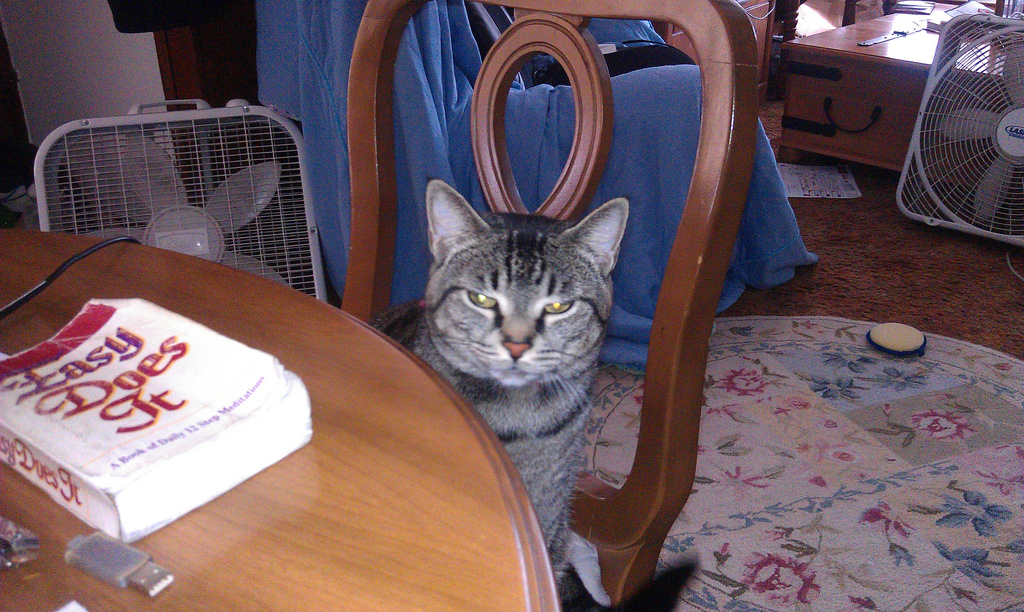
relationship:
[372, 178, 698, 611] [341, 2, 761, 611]
cat sitting on chair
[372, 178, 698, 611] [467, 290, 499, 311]
cat with eye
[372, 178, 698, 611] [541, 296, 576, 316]
cat with eye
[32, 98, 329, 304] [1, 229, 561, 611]
box fan sitting behind table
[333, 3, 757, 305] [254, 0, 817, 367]
chair covered in blanket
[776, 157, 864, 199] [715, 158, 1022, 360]
paper sitting on floor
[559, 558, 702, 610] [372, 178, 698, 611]
tail of cat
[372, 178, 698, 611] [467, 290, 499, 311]
cat has eye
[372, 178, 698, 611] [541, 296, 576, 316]
cat has eye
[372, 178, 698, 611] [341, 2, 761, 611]
cat sitting in chair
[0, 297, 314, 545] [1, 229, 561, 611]
book sitting on table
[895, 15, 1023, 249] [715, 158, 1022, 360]
fan sitting on floor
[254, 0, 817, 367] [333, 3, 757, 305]
blanket covering over chair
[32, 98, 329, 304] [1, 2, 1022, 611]
box fan sitting in room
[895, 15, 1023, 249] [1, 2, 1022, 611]
fan sitting in room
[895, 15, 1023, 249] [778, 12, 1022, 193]
fan leaning on chest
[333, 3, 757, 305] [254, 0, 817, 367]
chair covered with blanket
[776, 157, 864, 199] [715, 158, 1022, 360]
paper lying on floor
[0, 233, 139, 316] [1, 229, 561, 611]
cord draped over table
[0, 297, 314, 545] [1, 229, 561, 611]
book laying on table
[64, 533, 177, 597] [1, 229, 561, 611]
usb drive sitting on table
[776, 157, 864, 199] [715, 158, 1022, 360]
paper laying on floor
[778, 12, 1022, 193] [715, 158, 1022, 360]
chest sitting on floor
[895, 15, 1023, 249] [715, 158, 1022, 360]
fan sits on floor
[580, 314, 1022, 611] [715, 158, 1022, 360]
rug laying on floor